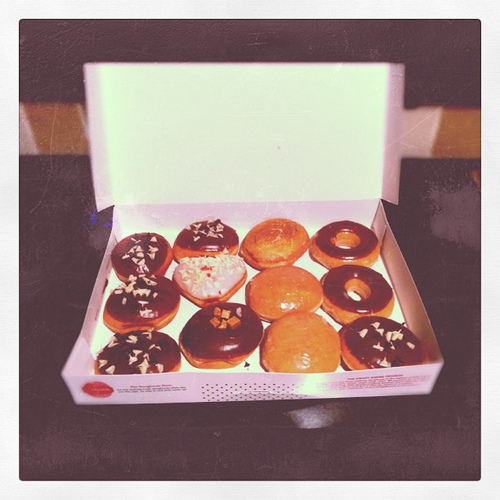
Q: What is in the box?
A: Doughnuts.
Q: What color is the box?
A: Pink.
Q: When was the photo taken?
A: When the box was full.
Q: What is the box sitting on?
A: A counter.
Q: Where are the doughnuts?
A: In the box.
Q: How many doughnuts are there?
A: Twelve.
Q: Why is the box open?
A: To see the doughnuts.